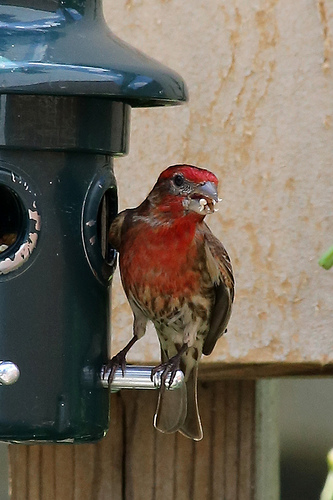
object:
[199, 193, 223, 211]
feed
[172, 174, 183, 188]
eye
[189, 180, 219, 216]
beak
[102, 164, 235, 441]
bird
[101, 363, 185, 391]
perch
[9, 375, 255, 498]
fence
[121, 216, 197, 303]
patch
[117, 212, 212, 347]
body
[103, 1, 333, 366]
wall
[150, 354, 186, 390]
claw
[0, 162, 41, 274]
shape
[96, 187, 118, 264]
hole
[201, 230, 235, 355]
left wing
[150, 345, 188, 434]
tail feather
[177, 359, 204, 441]
tail feather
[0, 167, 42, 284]
paint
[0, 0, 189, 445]
bird feeder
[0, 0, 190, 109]
cover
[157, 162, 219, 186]
top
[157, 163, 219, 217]
bird head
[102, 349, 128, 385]
claw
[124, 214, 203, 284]
chest